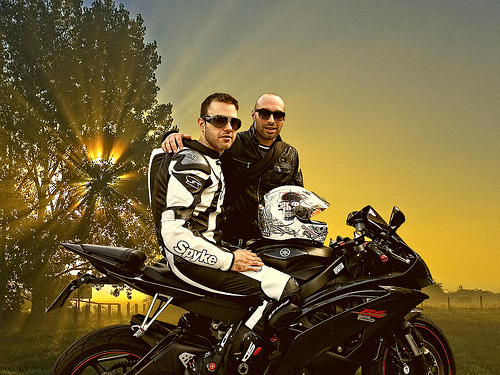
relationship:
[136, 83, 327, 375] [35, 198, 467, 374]
men posing with black motorcycle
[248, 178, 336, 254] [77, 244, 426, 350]
helmet for motorcycle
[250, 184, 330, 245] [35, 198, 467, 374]
helmet on black motorcycle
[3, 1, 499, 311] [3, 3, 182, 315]
sunset behind tree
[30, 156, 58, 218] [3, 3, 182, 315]
branches on tree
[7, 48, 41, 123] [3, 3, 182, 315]
branches on tree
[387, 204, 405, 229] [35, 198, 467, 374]
mirror on black motorcycle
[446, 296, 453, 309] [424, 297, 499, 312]
rod on fencing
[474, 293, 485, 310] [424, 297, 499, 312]
rod on fencing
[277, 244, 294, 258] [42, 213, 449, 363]
logo on bike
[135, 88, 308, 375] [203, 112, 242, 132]
man wearing sunglasses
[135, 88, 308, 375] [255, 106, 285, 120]
man wearing sunglasses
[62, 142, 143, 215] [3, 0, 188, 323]
sun behind tree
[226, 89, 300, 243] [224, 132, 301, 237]
man wearing jacket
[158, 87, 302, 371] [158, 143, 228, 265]
man wearing jacket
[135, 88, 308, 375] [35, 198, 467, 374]
man sitting on black motorcycle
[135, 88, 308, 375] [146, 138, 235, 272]
man wearing jacket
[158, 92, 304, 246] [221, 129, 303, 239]
man wearing jacket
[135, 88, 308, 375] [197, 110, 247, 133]
man wearing sunglasses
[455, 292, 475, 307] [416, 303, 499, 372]
cow standing in pasture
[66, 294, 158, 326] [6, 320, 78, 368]
fence surrounding pasture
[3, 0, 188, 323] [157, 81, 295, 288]
tree behind man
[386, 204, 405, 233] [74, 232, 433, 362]
light on motorcycle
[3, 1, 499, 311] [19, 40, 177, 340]
sunset shining through trees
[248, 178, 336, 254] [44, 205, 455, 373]
helmet on bike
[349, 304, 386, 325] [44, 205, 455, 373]
logo on bike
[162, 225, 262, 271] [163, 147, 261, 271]
word spyke on arm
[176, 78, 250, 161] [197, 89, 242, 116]
head with hair